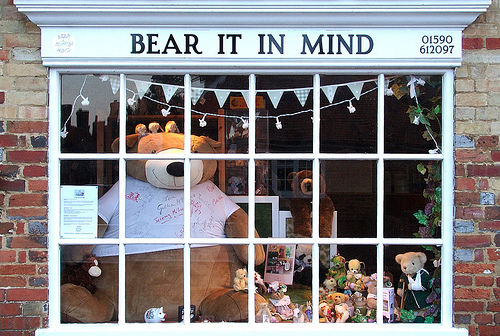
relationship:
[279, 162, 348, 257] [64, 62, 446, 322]
bear behind window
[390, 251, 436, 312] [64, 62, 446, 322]
bear behind window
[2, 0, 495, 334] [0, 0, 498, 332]
bricks in building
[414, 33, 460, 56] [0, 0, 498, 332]
numbers on building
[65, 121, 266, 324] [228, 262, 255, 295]
bear in lap of bear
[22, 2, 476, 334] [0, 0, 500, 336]
window at building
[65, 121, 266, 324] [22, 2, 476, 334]
bear in window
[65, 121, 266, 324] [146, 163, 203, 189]
bear with a smile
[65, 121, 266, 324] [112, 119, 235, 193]
bear with a face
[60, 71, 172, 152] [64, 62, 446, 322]
reflection in window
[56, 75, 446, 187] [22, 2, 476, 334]
lights hanging down on window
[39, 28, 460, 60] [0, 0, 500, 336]
sign for building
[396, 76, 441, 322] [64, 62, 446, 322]
vine on window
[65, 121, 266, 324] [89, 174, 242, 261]
bear wears shirt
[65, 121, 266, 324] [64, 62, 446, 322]
bear through window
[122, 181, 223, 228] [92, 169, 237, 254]
writing on shirt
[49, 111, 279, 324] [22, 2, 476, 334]
bear in window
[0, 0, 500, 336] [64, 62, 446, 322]
building has window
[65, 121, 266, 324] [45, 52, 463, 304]
bear in window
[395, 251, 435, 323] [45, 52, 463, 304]
bear in window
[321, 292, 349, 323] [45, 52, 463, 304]
bear in window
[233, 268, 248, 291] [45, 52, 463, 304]
bear in window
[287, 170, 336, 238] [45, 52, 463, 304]
bear in window